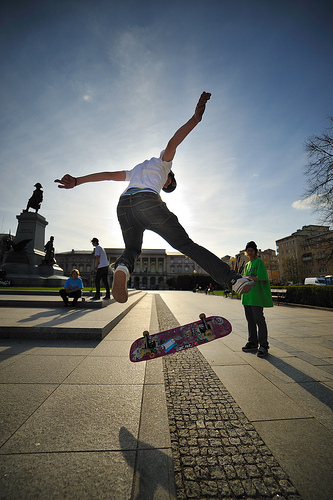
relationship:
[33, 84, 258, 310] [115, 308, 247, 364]
boy on skateboard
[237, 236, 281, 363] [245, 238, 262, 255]
boy wears cap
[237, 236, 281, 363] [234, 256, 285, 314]
boy wears shirt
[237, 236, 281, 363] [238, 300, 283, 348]
boy wears pants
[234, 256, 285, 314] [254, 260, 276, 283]
shirt has sleeve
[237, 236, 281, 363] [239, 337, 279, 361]
boy wears shoes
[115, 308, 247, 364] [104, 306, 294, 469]
skateboard in air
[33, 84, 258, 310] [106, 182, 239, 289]
boy wears pants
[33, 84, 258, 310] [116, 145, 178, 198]
boy wears shirt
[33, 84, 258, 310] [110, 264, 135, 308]
boy wears shoe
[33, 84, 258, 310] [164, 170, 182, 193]
boy wears cap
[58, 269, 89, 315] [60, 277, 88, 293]
boy wears shirt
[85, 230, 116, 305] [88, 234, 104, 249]
boy wears hat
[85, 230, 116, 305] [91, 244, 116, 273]
boy wears shirt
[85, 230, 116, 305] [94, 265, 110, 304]
boy wears pants